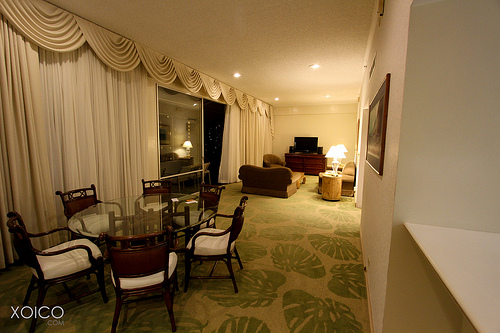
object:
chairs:
[6, 211, 179, 332]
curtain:
[0, 0, 275, 267]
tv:
[293, 136, 319, 153]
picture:
[364, 72, 392, 178]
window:
[203, 99, 228, 182]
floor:
[250, 196, 362, 332]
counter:
[401, 221, 499, 332]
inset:
[402, 222, 499, 332]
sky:
[204, 97, 226, 161]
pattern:
[253, 207, 348, 330]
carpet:
[244, 240, 362, 332]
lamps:
[323, 144, 348, 175]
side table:
[320, 173, 343, 202]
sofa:
[237, 153, 306, 199]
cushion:
[30, 238, 103, 280]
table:
[67, 193, 221, 240]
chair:
[183, 195, 251, 292]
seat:
[110, 250, 178, 289]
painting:
[363, 72, 391, 176]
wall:
[360, 0, 411, 332]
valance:
[39, 1, 277, 107]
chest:
[283, 152, 328, 176]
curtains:
[174, 61, 275, 183]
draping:
[220, 82, 272, 118]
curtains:
[0, 0, 142, 71]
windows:
[158, 87, 229, 196]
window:
[157, 86, 201, 200]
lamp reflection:
[180, 138, 196, 157]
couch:
[237, 164, 301, 199]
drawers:
[285, 156, 327, 175]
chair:
[103, 230, 179, 332]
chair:
[6, 211, 111, 318]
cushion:
[186, 226, 238, 256]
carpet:
[189, 184, 372, 332]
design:
[267, 239, 327, 280]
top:
[104, 197, 172, 235]